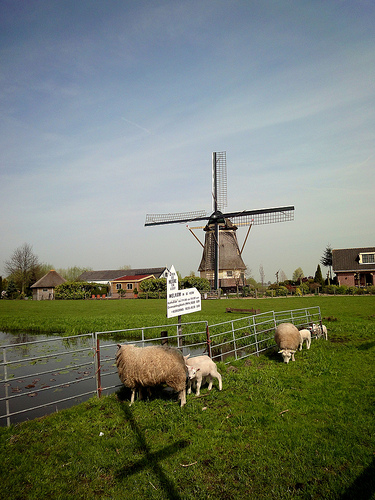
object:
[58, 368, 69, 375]
leaves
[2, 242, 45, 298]
tree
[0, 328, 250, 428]
pond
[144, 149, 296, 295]
mill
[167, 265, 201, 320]
board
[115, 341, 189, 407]
ram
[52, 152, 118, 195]
clouds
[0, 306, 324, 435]
fence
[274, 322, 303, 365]
sheep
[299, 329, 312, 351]
sheep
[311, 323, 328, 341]
sheep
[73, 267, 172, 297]
house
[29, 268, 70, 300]
house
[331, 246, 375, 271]
roof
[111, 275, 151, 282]
roof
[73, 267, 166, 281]
roof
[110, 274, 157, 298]
building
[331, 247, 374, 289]
building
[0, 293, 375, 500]
grass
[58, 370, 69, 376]
lily pad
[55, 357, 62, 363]
lily pad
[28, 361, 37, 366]
lily pad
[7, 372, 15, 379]
lily pad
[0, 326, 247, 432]
water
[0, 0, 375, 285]
sky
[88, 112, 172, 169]
clouds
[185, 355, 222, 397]
kid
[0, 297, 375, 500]
field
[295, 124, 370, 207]
clouds